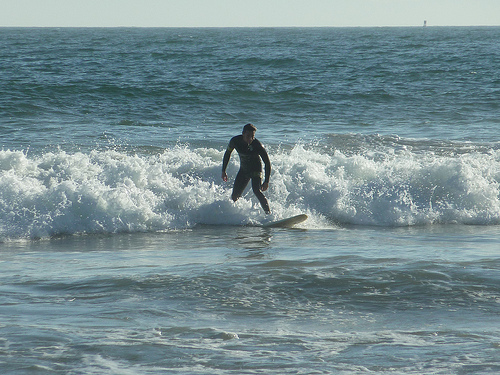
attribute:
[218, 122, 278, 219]
man — crouched, standing, wet, surfing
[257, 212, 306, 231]
surfboard — white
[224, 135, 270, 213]
wetsuit — black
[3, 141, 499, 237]
wave — white, cresting, breaking, splashing, forming, small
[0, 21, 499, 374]
water — rambunctious, zealous, aggressive, blue, boisterous, choppy, wavy, vast, splashing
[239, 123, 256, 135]
hair — short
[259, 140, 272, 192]
arm — down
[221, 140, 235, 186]
arm — down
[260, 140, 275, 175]
sleeve — long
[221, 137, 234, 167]
sleeve — long